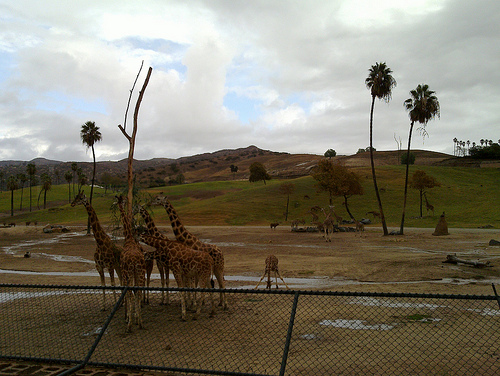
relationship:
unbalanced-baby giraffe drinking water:
[251, 254, 290, 290] [230, 265, 343, 308]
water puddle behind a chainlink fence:
[319, 313, 407, 330] [0, 282, 499, 376]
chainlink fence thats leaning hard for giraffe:
[0, 276, 464, 371] [63, 180, 236, 332]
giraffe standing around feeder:
[69, 189, 125, 312] [103, 163, 151, 236]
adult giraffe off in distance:
[417, 185, 437, 214] [237, 173, 474, 222]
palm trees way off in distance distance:
[452, 134, 483, 157] [286, 100, 485, 160]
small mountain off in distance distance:
[222, 140, 275, 160] [89, 139, 374, 180]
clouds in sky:
[0, 0, 498, 160] [0, 0, 498, 164]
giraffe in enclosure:
[67, 187, 125, 314] [7, 147, 498, 374]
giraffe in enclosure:
[113, 193, 148, 335] [7, 147, 498, 374]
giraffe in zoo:
[67, 187, 125, 314] [1, 283, 498, 373]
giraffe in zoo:
[108, 189, 147, 333] [1, 283, 498, 373]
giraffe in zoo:
[138, 233, 212, 319] [1, 283, 498, 373]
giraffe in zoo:
[113, 193, 148, 335] [1, 283, 498, 373]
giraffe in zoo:
[152, 191, 226, 317] [1, 283, 498, 373]